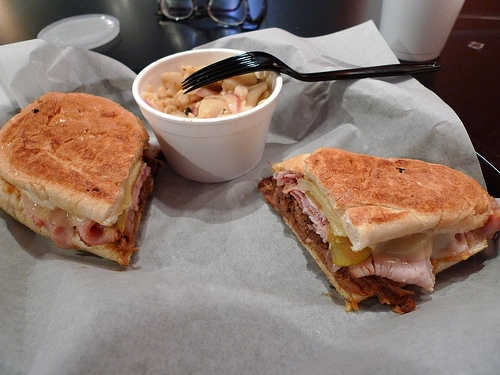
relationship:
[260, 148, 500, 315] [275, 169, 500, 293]
panini has ham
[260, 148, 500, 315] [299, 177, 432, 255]
panini has cheese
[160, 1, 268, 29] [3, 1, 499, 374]
eyeglasses are on top of table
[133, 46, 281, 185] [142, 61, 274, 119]
cup has pasta salad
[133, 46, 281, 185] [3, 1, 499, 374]
cup on top of table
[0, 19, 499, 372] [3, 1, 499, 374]
paper on top of table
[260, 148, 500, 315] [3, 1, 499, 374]
panini on top of table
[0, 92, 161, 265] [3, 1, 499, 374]
panini on top of table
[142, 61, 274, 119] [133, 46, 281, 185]
pasta salad in cup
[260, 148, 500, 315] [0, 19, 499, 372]
panini on top of paper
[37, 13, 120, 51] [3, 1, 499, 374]
lid on top of table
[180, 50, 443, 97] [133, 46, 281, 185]
fork on top of cup